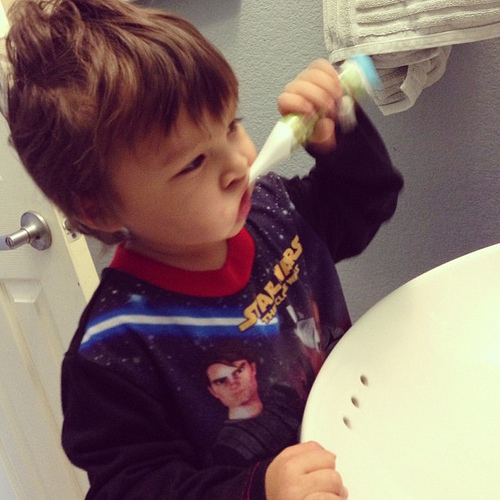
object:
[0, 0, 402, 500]
boy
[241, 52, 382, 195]
brush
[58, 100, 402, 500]
shirt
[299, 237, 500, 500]
sink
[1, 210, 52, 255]
knob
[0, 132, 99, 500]
door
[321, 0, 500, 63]
towel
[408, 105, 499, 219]
wall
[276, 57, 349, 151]
hand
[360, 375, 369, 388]
holes